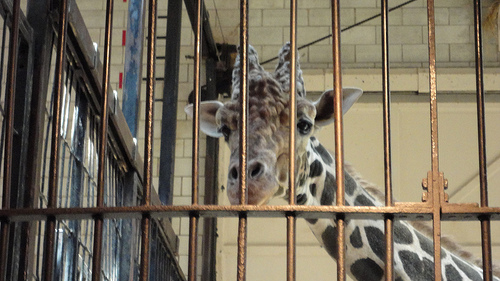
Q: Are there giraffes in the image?
A: Yes, there is a giraffe.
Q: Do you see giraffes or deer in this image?
A: Yes, there is a giraffe.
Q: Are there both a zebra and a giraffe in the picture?
A: No, there is a giraffe but no zebras.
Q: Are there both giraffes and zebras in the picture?
A: No, there is a giraffe but no zebras.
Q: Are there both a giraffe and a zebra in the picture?
A: No, there is a giraffe but no zebras.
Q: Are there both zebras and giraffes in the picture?
A: No, there is a giraffe but no zebras.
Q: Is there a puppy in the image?
A: No, there are no puppys.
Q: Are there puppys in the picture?
A: No, there are no puppys.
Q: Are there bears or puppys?
A: No, there are no puppys or bears.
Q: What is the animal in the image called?
A: The animal is a giraffe.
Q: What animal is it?
A: The animal is a giraffe.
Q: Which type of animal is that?
A: This is a giraffe.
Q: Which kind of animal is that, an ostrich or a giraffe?
A: This is a giraffe.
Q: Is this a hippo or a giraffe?
A: This is a giraffe.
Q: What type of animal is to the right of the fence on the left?
A: The animal is a giraffe.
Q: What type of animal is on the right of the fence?
A: The animal is a giraffe.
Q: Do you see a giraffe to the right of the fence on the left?
A: Yes, there is a giraffe to the right of the fence.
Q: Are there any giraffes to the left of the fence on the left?
A: No, the giraffe is to the right of the fence.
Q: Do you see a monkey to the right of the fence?
A: No, there is a giraffe to the right of the fence.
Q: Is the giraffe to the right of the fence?
A: Yes, the giraffe is to the right of the fence.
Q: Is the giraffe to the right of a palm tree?
A: No, the giraffe is to the right of the fence.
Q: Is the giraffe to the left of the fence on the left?
A: No, the giraffe is to the right of the fence.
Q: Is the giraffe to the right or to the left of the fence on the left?
A: The giraffe is to the right of the fence.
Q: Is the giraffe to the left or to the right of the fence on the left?
A: The giraffe is to the right of the fence.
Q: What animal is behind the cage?
A: The animal is a giraffe.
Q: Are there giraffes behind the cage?
A: Yes, there is a giraffe behind the cage.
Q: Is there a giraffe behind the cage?
A: Yes, there is a giraffe behind the cage.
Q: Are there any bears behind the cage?
A: No, there is a giraffe behind the cage.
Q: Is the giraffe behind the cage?
A: Yes, the giraffe is behind the cage.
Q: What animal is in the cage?
A: The giraffe is in the cage.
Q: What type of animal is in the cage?
A: The animal is a giraffe.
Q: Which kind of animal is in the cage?
A: The animal is a giraffe.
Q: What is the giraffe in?
A: The giraffe is in the cage.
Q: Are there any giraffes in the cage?
A: Yes, there is a giraffe in the cage.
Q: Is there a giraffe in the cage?
A: Yes, there is a giraffe in the cage.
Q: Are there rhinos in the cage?
A: No, there is a giraffe in the cage.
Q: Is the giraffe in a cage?
A: Yes, the giraffe is in a cage.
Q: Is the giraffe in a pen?
A: No, the giraffe is in a cage.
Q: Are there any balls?
A: No, there are no balls.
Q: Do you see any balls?
A: No, there are no balls.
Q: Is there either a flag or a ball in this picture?
A: No, there are no balls or flags.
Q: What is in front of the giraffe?
A: The cage is in front of the giraffe.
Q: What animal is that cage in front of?
A: The cage is in front of the giraffe.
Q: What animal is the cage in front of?
A: The cage is in front of the giraffe.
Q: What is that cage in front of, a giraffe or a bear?
A: The cage is in front of a giraffe.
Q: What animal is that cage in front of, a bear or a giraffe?
A: The cage is in front of a giraffe.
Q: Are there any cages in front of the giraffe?
A: Yes, there is a cage in front of the giraffe.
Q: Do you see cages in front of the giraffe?
A: Yes, there is a cage in front of the giraffe.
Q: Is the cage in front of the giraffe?
A: Yes, the cage is in front of the giraffe.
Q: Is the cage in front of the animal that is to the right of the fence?
A: Yes, the cage is in front of the giraffe.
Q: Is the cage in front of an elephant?
A: No, the cage is in front of the giraffe.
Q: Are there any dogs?
A: No, there are no dogs.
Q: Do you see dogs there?
A: No, there are no dogs.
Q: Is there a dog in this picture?
A: No, there are no dogs.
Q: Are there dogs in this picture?
A: No, there are no dogs.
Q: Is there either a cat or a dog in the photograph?
A: No, there are no dogs or cats.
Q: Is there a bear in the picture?
A: No, there are no bears.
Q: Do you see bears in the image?
A: No, there are no bears.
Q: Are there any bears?
A: No, there are no bears.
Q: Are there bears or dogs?
A: No, there are no bears or dogs.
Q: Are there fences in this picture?
A: Yes, there is a fence.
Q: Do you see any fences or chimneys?
A: Yes, there is a fence.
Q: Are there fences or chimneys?
A: Yes, there is a fence.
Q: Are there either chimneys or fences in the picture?
A: Yes, there is a fence.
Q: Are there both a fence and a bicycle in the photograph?
A: No, there is a fence but no bicycles.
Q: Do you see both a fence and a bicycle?
A: No, there is a fence but no bicycles.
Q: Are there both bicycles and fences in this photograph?
A: No, there is a fence but no bicycles.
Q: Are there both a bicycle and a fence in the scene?
A: No, there is a fence but no bicycles.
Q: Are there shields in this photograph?
A: No, there are no shields.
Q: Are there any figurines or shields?
A: No, there are no shields or figurines.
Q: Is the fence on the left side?
A: Yes, the fence is on the left of the image.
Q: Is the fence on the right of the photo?
A: No, the fence is on the left of the image.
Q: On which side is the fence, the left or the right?
A: The fence is on the left of the image.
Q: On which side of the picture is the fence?
A: The fence is on the left of the image.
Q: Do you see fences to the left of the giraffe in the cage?
A: Yes, there is a fence to the left of the giraffe.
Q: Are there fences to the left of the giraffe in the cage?
A: Yes, there is a fence to the left of the giraffe.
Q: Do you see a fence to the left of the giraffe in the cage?
A: Yes, there is a fence to the left of the giraffe.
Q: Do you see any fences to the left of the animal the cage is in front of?
A: Yes, there is a fence to the left of the giraffe.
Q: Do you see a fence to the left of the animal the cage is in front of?
A: Yes, there is a fence to the left of the giraffe.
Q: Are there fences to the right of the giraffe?
A: No, the fence is to the left of the giraffe.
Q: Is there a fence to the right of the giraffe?
A: No, the fence is to the left of the giraffe.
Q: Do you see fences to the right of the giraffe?
A: No, the fence is to the left of the giraffe.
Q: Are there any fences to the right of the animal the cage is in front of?
A: No, the fence is to the left of the giraffe.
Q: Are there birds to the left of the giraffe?
A: No, there is a fence to the left of the giraffe.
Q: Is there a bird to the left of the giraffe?
A: No, there is a fence to the left of the giraffe.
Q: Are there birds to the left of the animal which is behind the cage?
A: No, there is a fence to the left of the giraffe.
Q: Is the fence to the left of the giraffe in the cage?
A: Yes, the fence is to the left of the giraffe.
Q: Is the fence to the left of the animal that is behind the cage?
A: Yes, the fence is to the left of the giraffe.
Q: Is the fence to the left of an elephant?
A: No, the fence is to the left of the giraffe.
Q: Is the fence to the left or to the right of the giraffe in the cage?
A: The fence is to the left of the giraffe.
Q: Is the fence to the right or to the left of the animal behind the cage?
A: The fence is to the left of the giraffe.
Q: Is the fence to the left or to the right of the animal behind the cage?
A: The fence is to the left of the giraffe.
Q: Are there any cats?
A: No, there are no cats.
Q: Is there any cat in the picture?
A: No, there are no cats.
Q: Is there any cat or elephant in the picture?
A: No, there are no cats or elephants.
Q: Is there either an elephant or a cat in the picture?
A: No, there are no cats or elephants.